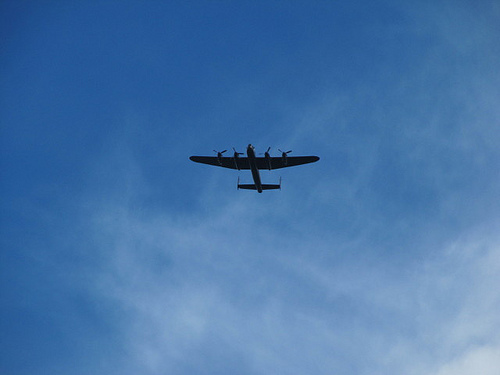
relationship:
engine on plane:
[217, 150, 226, 160] [189, 144, 319, 196]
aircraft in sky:
[185, 140, 325, 198] [129, 69, 380, 274]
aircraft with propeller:
[185, 140, 325, 198] [230, 145, 244, 163]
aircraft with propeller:
[185, 140, 325, 198] [211, 147, 228, 161]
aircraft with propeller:
[185, 140, 325, 198] [260, 143, 273, 160]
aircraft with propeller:
[185, 140, 325, 198] [275, 143, 293, 161]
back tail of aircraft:
[234, 176, 285, 193] [185, 140, 325, 198]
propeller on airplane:
[228, 144, 245, 159] [170, 102, 335, 219]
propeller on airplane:
[260, 143, 273, 162] [193, 139, 319, 195]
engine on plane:
[226, 149, 243, 172] [173, 132, 332, 212]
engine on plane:
[267, 148, 297, 179] [108, 118, 387, 214]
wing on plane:
[256, 149, 317, 170] [189, 144, 319, 196]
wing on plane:
[191, 151, 252, 170] [189, 144, 319, 196]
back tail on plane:
[234, 176, 285, 193] [185, 132, 345, 211]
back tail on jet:
[234, 176, 285, 193] [193, 137, 315, 198]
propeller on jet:
[277, 145, 294, 157] [183, 111, 343, 236]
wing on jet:
[191, 151, 252, 170] [171, 129, 333, 213]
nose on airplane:
[246, 142, 256, 160] [188, 144, 323, 193]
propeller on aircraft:
[277, 146, 294, 158] [187, 142, 320, 193]